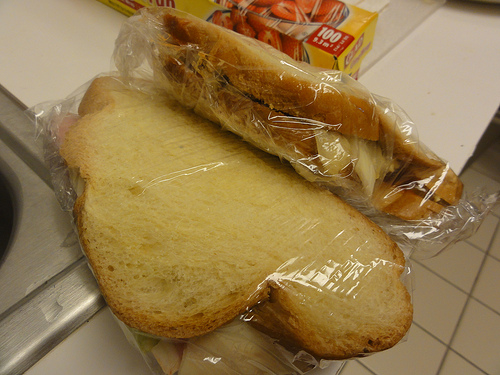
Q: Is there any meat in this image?
A: Yes, there is meat.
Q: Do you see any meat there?
A: Yes, there is meat.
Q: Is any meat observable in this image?
A: Yes, there is meat.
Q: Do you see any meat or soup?
A: Yes, there is meat.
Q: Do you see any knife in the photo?
A: No, there are no knives.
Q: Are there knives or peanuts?
A: No, there are no knives or peanuts.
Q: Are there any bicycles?
A: No, there are no bicycles.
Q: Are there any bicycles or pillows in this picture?
A: No, there are no bicycles or pillows.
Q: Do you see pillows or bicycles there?
A: No, there are no bicycles or pillows.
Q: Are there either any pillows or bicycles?
A: No, there are no bicycles or pillows.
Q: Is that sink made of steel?
A: Yes, the sink is made of steel.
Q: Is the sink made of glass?
A: No, the sink is made of steel.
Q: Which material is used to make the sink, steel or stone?
A: The sink is made of steel.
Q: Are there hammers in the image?
A: No, there are no hammers.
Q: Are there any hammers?
A: No, there are no hammers.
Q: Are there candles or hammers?
A: No, there are no hammers or candles.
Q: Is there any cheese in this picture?
A: Yes, there is cheese.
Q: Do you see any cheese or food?
A: Yes, there is cheese.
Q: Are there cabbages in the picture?
A: No, there are no cabbages.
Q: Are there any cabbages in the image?
A: No, there are no cabbages.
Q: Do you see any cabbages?
A: No, there are no cabbages.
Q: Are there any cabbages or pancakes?
A: No, there are no cabbages or pancakes.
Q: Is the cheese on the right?
A: Yes, the cheese is on the right of the image.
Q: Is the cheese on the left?
A: No, the cheese is on the right of the image.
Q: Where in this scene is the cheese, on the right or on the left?
A: The cheese is on the right of the image.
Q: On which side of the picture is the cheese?
A: The cheese is on the right of the image.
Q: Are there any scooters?
A: No, there are no scooters.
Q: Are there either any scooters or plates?
A: No, there are no scooters or plates.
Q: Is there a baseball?
A: No, there are no baseballs.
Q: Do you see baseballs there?
A: No, there are no baseballs.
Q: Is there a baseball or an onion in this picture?
A: No, there are no baseballs or onions.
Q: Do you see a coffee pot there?
A: No, there are no coffee pots.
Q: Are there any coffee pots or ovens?
A: No, there are no coffee pots or ovens.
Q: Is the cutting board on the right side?
A: Yes, the cutting board is on the right of the image.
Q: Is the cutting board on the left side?
A: No, the cutting board is on the right of the image.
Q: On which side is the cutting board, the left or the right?
A: The cutting board is on the right of the image.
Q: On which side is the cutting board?
A: The cutting board is on the right of the image.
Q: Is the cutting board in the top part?
A: Yes, the cutting board is in the top of the image.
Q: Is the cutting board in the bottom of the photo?
A: No, the cutting board is in the top of the image.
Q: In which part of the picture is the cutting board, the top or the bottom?
A: The cutting board is in the top of the image.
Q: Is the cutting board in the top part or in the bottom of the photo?
A: The cutting board is in the top of the image.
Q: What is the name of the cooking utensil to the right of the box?
A: The cooking utensil is a cutting board.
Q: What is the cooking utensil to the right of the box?
A: The cooking utensil is a cutting board.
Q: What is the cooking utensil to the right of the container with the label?
A: The cooking utensil is a cutting board.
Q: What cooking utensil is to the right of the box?
A: The cooking utensil is a cutting board.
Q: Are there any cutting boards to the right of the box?
A: Yes, there is a cutting board to the right of the box.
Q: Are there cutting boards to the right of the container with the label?
A: Yes, there is a cutting board to the right of the box.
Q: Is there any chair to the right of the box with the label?
A: No, there is a cutting board to the right of the box.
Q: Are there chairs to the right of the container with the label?
A: No, there is a cutting board to the right of the box.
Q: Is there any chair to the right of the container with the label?
A: No, there is a cutting board to the right of the box.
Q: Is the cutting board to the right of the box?
A: Yes, the cutting board is to the right of the box.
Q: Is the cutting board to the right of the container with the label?
A: Yes, the cutting board is to the right of the box.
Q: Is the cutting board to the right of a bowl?
A: No, the cutting board is to the right of the box.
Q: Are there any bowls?
A: No, there are no bowls.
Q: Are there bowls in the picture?
A: No, there are no bowls.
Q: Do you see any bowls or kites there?
A: No, there are no bowls or kites.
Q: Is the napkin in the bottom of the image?
A: Yes, the napkin is in the bottom of the image.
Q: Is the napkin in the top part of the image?
A: No, the napkin is in the bottom of the image.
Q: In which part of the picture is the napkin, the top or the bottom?
A: The napkin is in the bottom of the image.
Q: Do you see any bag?
A: Yes, there is a bag.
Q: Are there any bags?
A: Yes, there is a bag.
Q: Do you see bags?
A: Yes, there is a bag.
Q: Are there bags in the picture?
A: Yes, there is a bag.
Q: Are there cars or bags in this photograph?
A: Yes, there is a bag.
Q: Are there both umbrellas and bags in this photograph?
A: No, there is a bag but no umbrellas.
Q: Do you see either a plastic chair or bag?
A: Yes, there is a plastic bag.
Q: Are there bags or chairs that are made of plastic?
A: Yes, the bag is made of plastic.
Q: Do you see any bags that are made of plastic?
A: Yes, there is a bag that is made of plastic.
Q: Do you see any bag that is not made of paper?
A: Yes, there is a bag that is made of plastic.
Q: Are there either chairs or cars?
A: No, there are no cars or chairs.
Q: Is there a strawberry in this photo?
A: Yes, there are strawberries.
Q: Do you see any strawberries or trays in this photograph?
A: Yes, there are strawberries.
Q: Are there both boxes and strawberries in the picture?
A: Yes, there are both strawberries and a box.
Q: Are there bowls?
A: No, there are no bowls.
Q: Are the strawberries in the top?
A: Yes, the strawberries are in the top of the image.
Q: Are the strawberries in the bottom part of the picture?
A: No, the strawberries are in the top of the image.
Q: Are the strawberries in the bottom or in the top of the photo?
A: The strawberries are in the top of the image.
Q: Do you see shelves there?
A: No, there are no shelves.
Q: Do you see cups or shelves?
A: No, there are no shelves or cups.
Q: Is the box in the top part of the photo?
A: Yes, the box is in the top of the image.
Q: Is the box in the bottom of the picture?
A: No, the box is in the top of the image.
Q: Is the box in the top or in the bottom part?
A: The box is in the top of the image.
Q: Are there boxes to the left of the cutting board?
A: Yes, there is a box to the left of the cutting board.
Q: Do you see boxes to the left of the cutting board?
A: Yes, there is a box to the left of the cutting board.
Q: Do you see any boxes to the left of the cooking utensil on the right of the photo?
A: Yes, there is a box to the left of the cutting board.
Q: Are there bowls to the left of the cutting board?
A: No, there is a box to the left of the cutting board.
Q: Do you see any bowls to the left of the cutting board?
A: No, there is a box to the left of the cutting board.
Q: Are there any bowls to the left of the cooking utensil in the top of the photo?
A: No, there is a box to the left of the cutting board.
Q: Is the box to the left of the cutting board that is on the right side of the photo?
A: Yes, the box is to the left of the cutting board.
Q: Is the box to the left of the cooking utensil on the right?
A: Yes, the box is to the left of the cutting board.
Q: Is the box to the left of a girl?
A: No, the box is to the left of the cutting board.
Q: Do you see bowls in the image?
A: No, there are no bowls.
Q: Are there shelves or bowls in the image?
A: No, there are no bowls or shelves.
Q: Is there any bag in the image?
A: Yes, there is a bag.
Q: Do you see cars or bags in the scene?
A: Yes, there is a bag.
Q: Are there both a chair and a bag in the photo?
A: No, there is a bag but no chairs.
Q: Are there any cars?
A: No, there are no cars.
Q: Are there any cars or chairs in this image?
A: No, there are no cars or chairs.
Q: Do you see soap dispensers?
A: No, there are no soap dispensers.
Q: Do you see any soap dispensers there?
A: No, there are no soap dispensers.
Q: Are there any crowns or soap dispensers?
A: No, there are no soap dispensers or crowns.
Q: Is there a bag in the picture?
A: Yes, there is a bag.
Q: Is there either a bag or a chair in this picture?
A: Yes, there is a bag.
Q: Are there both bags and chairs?
A: No, there is a bag but no chairs.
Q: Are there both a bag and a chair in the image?
A: No, there is a bag but no chairs.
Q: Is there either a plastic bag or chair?
A: Yes, there is a plastic bag.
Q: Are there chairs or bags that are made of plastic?
A: Yes, the bag is made of plastic.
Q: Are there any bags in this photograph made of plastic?
A: Yes, there is a bag that is made of plastic.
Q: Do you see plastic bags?
A: Yes, there is a bag that is made of plastic.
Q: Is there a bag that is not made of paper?
A: Yes, there is a bag that is made of plastic.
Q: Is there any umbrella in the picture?
A: No, there are no umbrellas.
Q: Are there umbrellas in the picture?
A: No, there are no umbrellas.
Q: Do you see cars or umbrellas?
A: No, there are no umbrellas or cars.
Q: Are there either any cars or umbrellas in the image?
A: No, there are no umbrellas or cars.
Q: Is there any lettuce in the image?
A: Yes, there is lettuce.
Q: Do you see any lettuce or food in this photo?
A: Yes, there is lettuce.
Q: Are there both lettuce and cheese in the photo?
A: Yes, there are both lettuce and cheese.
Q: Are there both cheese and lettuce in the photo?
A: Yes, there are both lettuce and cheese.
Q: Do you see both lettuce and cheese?
A: Yes, there are both lettuce and cheese.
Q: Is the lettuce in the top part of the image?
A: Yes, the lettuce is in the top of the image.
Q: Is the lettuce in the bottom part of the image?
A: No, the lettuce is in the top of the image.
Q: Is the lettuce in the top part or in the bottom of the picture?
A: The lettuce is in the top of the image.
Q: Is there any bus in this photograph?
A: No, there are no buses.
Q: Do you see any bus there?
A: No, there are no buses.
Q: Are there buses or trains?
A: No, there are no buses or trains.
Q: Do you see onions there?
A: No, there are no onions.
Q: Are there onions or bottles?
A: No, there are no onions or bottles.